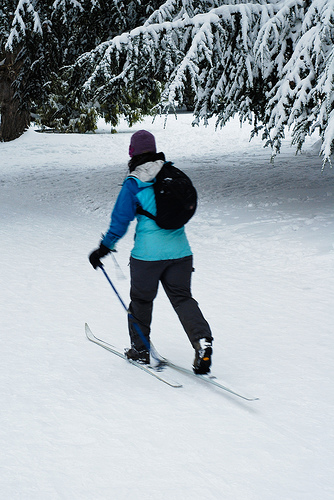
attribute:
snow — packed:
[147, 11, 320, 93]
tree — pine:
[13, 4, 327, 119]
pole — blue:
[96, 258, 164, 367]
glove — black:
[85, 244, 117, 270]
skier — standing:
[90, 127, 221, 382]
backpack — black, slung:
[145, 161, 199, 231]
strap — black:
[134, 204, 153, 222]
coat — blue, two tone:
[106, 166, 194, 263]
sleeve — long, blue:
[97, 176, 141, 245]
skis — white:
[78, 316, 264, 406]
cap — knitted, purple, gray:
[125, 130, 159, 157]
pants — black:
[132, 253, 208, 349]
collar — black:
[123, 150, 171, 165]